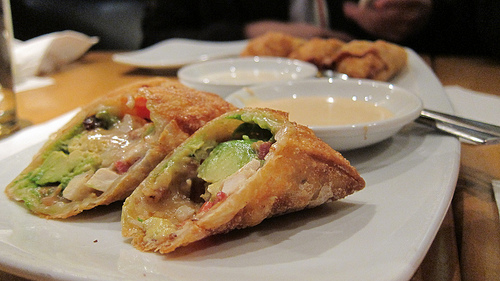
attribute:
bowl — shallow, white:
[260, 72, 401, 142]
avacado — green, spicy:
[209, 134, 251, 168]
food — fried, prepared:
[103, 59, 354, 253]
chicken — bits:
[95, 129, 146, 168]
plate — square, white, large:
[344, 206, 431, 276]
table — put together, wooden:
[64, 60, 112, 98]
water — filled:
[3, 46, 18, 126]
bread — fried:
[365, 40, 405, 71]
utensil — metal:
[426, 89, 499, 155]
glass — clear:
[1, 36, 16, 132]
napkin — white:
[42, 24, 89, 65]